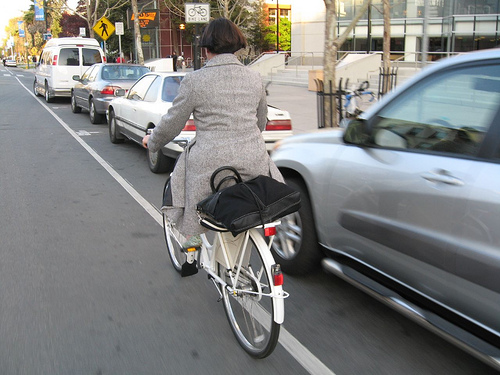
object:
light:
[101, 85, 122, 96]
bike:
[320, 80, 376, 123]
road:
[3, 63, 494, 372]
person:
[140, 18, 283, 277]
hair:
[199, 16, 247, 55]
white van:
[32, 35, 108, 104]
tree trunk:
[317, 0, 340, 127]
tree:
[87, 0, 159, 55]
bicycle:
[143, 124, 291, 359]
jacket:
[147, 53, 287, 248]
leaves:
[266, 17, 291, 50]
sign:
[88, 16, 116, 43]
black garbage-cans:
[310, 71, 353, 136]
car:
[103, 69, 297, 178]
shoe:
[181, 258, 199, 277]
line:
[2, 60, 337, 375]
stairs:
[261, 77, 310, 89]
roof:
[292, 17, 328, 27]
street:
[0, 61, 499, 372]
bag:
[196, 165, 305, 236]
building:
[319, 0, 499, 127]